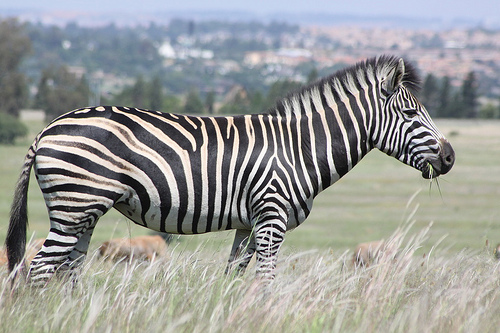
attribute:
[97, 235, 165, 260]
animal — brown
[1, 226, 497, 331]
field — large, open, green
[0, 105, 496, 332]
grass — wheat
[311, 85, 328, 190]
stripe — black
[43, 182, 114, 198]
stripe — black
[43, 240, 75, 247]
stripe — black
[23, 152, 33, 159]
stripe — black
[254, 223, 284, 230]
stripe — black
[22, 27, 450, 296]
zebra — grazing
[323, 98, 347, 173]
stripe — black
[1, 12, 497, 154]
trees — blurred, pine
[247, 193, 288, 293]
leg — front right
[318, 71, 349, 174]
stripe — black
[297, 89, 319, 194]
stripe — black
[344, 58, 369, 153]
stripe — black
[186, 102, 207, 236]
stripe — black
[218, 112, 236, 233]
stripe — black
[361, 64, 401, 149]
stripe — black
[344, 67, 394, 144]
stripe — black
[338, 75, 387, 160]
stripe — black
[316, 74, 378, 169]
stripe — black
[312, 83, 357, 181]
stripe — black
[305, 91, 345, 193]
stripe — black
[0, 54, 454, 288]
zebra — back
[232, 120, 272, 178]
stripe — black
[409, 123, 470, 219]
nose — black 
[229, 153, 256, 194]
stripe — black 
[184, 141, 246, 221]
stripe — black 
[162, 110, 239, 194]
stripe — black 